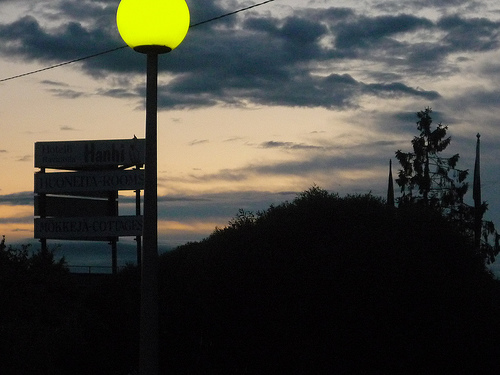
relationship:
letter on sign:
[80, 145, 155, 160] [27, 119, 162, 183]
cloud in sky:
[11, 1, 473, 108] [1, 1, 498, 278]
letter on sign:
[83, 143, 96, 165] [32, 137, 143, 168]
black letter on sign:
[102, 147, 116, 164] [26, 128, 158, 167]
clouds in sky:
[9, 3, 498, 115] [1, 2, 498, 204]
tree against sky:
[399, 109, 491, 266] [1, 1, 498, 278]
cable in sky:
[0, 0, 273, 88] [1, 1, 498, 278]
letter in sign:
[86, 144, 107, 165] [82, 67, 493, 112]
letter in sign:
[99, 140, 130, 165] [32, 138, 151, 169]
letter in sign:
[31, 167, 51, 195] [20, 129, 152, 264]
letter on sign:
[83, 170, 96, 189] [24, 134, 164, 246]